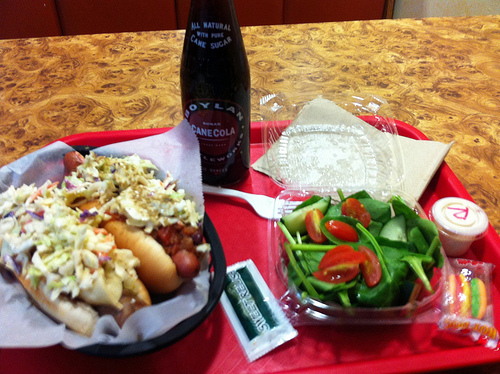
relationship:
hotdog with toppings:
[66, 149, 207, 287] [80, 152, 195, 242]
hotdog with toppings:
[10, 191, 148, 348] [11, 195, 116, 295]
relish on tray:
[224, 263, 285, 360] [48, 125, 485, 373]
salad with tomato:
[282, 195, 432, 298] [302, 213, 343, 247]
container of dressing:
[437, 197, 489, 256] [427, 195, 491, 258]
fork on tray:
[197, 181, 278, 220] [48, 125, 485, 373]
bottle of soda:
[181, 1, 255, 192] [220, 67, 223, 71]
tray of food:
[48, 125, 485, 373] [10, 158, 198, 330]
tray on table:
[48, 125, 485, 373] [4, 20, 499, 374]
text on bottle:
[195, 23, 231, 32] [181, 1, 255, 192]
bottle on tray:
[181, 1, 255, 192] [48, 125, 485, 373]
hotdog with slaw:
[66, 149, 207, 287] [80, 152, 195, 242]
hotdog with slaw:
[10, 191, 148, 348] [11, 195, 116, 295]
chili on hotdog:
[157, 224, 202, 256] [66, 149, 207, 287]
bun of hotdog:
[110, 224, 173, 281] [66, 149, 207, 287]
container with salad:
[265, 91, 453, 316] [282, 195, 432, 298]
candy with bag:
[448, 268, 499, 333] [456, 258, 481, 276]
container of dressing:
[437, 197, 489, 256] [466, 223, 471, 226]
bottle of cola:
[181, 1, 255, 192] [218, 129, 233, 140]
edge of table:
[9, 27, 185, 42] [4, 20, 499, 374]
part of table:
[52, 68, 55, 72] [4, 20, 499, 374]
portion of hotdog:
[190, 263, 199, 271] [66, 149, 207, 287]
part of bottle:
[198, 5, 201, 10] [181, 1, 255, 192]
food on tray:
[10, 158, 198, 330] [48, 125, 485, 373]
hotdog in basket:
[66, 149, 207, 287] [95, 233, 228, 353]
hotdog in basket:
[10, 191, 148, 348] [95, 233, 228, 353]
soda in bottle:
[220, 67, 223, 71] [181, 1, 255, 192]